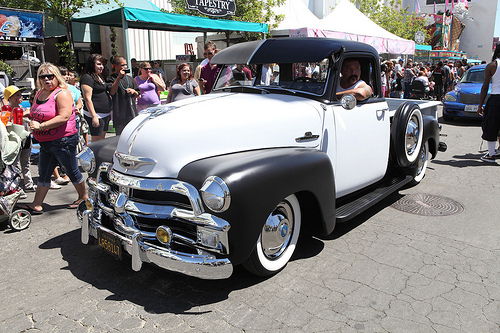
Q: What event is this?
A: Car parade.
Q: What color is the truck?
A: Black and white.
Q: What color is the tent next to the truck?
A: Green.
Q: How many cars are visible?
A: 2.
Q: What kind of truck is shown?
A: Old classic pick up.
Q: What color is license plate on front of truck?
A: Black and yellow.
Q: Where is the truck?
A: On the street.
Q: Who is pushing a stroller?
A: Blonde woman wearing a pink top.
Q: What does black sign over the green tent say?
A: Tapestry.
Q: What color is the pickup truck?
A: Black and white.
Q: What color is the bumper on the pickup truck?
A: Shiny silver.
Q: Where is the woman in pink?
A: Next to pickup truck.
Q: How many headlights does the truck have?
A: Two.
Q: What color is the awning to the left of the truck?
A: Green.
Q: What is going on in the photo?
A: A parade.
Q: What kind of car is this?
A: Antique.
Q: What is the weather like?
A: Sunny.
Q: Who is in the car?
A: A man.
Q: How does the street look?
A: Clean.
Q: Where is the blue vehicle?
A: Behind the car.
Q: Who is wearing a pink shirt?
A: A woman.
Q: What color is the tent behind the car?
A: White.